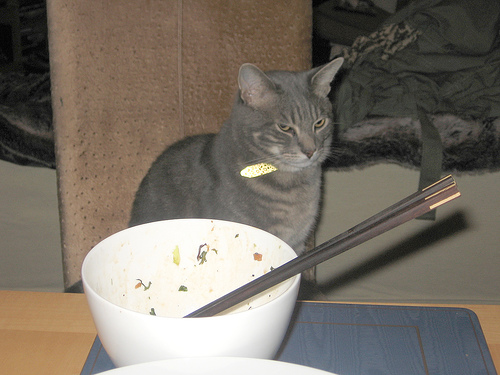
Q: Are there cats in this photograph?
A: Yes, there is a cat.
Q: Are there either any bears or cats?
A: Yes, there is a cat.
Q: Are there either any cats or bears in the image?
A: Yes, there is a cat.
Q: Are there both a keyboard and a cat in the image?
A: No, there is a cat but no keyboards.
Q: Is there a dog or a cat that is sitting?
A: Yes, the cat is sitting.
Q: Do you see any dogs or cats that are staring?
A: Yes, the cat is staring.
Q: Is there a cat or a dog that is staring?
A: Yes, the cat is staring.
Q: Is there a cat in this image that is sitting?
A: Yes, there is a cat that is sitting.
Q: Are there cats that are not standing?
A: Yes, there is a cat that is sitting.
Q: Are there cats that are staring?
A: Yes, there is a cat that is staring.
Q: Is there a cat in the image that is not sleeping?
A: Yes, there is a cat that is staring.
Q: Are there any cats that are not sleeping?
A: Yes, there is a cat that is staring.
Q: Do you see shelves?
A: No, there are no shelves.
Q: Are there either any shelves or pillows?
A: No, there are no shelves or pillows.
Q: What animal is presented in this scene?
A: The animal is a cat.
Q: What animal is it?
A: The animal is a cat.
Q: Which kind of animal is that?
A: That is a cat.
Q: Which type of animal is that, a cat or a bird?
A: That is a cat.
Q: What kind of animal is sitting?
A: The animal is a cat.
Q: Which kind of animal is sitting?
A: The animal is a cat.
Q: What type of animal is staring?
A: The animal is a cat.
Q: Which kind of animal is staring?
A: The animal is a cat.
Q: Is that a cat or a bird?
A: That is a cat.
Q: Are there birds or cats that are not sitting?
A: No, there is a cat but it is sitting.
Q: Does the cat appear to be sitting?
A: Yes, the cat is sitting.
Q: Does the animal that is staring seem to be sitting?
A: Yes, the cat is sitting.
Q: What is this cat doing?
A: The cat is sitting.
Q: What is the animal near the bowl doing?
A: The cat is sitting.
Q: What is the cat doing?
A: The cat is sitting.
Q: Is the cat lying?
A: No, the cat is sitting.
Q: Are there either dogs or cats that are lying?
A: No, there is a cat but it is sitting.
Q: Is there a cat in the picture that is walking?
A: No, there is a cat but it is sitting.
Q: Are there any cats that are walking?
A: No, there is a cat but it is sitting.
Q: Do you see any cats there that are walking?
A: No, there is a cat but it is sitting.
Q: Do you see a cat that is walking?
A: No, there is a cat but it is sitting.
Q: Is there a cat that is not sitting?
A: No, there is a cat but it is sitting.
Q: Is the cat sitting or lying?
A: The cat is sitting.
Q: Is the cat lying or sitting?
A: The cat is sitting.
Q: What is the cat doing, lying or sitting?
A: The cat is sitting.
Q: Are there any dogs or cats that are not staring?
A: No, there is a cat but it is staring.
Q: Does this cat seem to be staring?
A: Yes, the cat is staring.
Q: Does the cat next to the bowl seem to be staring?
A: Yes, the cat is staring.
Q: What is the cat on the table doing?
A: The cat is staring.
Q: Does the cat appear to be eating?
A: No, the cat is staring.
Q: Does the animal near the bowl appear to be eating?
A: No, the cat is staring.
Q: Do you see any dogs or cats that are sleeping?
A: No, there is a cat but it is staring.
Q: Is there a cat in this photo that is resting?
A: No, there is a cat but it is staring.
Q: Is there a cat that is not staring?
A: No, there is a cat but it is staring.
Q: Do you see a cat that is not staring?
A: No, there is a cat but it is staring.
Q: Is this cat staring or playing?
A: The cat is staring.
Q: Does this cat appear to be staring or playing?
A: The cat is staring.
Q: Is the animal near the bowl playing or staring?
A: The cat is staring.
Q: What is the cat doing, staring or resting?
A: The cat is staring.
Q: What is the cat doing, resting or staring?
A: The cat is staring.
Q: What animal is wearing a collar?
A: The cat is wearing a collar.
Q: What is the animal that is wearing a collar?
A: The animal is a cat.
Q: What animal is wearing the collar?
A: The animal is a cat.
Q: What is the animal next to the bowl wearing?
A: The cat is wearing a collar.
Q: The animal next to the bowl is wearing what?
A: The cat is wearing a collar.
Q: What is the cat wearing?
A: The cat is wearing a collar.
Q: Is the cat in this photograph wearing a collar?
A: Yes, the cat is wearing a collar.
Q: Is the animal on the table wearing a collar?
A: Yes, the cat is wearing a collar.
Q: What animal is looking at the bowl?
A: The cat is looking at the bowl.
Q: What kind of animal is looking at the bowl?
A: The animal is a cat.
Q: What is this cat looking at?
A: The cat is looking at the bowl.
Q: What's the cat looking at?
A: The cat is looking at the bowl.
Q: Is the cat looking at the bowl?
A: Yes, the cat is looking at the bowl.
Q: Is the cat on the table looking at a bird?
A: No, the cat is looking at the bowl.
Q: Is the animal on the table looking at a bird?
A: No, the cat is looking at the bowl.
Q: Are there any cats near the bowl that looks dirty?
A: Yes, there is a cat near the bowl.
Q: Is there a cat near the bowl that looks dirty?
A: Yes, there is a cat near the bowl.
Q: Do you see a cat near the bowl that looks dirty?
A: Yes, there is a cat near the bowl.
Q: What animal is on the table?
A: The cat is on the table.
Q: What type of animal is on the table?
A: The animal is a cat.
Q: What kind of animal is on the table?
A: The animal is a cat.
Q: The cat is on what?
A: The cat is on the table.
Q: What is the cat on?
A: The cat is on the table.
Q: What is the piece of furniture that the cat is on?
A: The piece of furniture is a table.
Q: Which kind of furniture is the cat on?
A: The cat is on the table.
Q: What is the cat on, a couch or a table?
A: The cat is on a table.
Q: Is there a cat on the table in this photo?
A: Yes, there is a cat on the table.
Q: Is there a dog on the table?
A: No, there is a cat on the table.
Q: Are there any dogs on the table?
A: No, there is a cat on the table.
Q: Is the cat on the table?
A: Yes, the cat is on the table.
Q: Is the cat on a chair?
A: No, the cat is on the table.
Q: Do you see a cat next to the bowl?
A: Yes, there is a cat next to the bowl.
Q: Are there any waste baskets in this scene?
A: No, there are no waste baskets.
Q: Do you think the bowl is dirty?
A: Yes, the bowl is dirty.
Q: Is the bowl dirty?
A: Yes, the bowl is dirty.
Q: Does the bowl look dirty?
A: Yes, the bowl is dirty.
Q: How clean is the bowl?
A: The bowl is dirty.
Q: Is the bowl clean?
A: No, the bowl is dirty.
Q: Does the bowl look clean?
A: No, the bowl is dirty.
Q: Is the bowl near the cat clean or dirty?
A: The bowl is dirty.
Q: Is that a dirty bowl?
A: Yes, that is a dirty bowl.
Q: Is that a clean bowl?
A: No, that is a dirty bowl.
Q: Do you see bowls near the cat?
A: Yes, there is a bowl near the cat.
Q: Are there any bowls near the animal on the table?
A: Yes, there is a bowl near the cat.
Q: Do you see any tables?
A: Yes, there is a table.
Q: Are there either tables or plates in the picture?
A: Yes, there is a table.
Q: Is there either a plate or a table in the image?
A: Yes, there is a table.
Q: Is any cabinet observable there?
A: No, there are no cabinets.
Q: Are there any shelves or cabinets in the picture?
A: No, there are no cabinets or shelves.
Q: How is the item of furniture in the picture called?
A: The piece of furniture is a table.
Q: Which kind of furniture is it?
A: The piece of furniture is a table.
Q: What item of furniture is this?
A: That is a table.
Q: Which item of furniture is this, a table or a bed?
A: That is a table.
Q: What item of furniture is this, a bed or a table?
A: That is a table.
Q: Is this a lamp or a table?
A: This is a table.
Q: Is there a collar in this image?
A: Yes, there is a collar.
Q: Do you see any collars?
A: Yes, there is a collar.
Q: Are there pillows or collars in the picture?
A: Yes, there is a collar.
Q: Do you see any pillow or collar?
A: Yes, there is a collar.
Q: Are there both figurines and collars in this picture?
A: No, there is a collar but no figurines.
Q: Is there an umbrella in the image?
A: No, there are no umbrellas.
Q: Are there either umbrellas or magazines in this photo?
A: No, there are no umbrellas or magazines.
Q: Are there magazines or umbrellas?
A: No, there are no umbrellas or magazines.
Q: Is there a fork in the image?
A: No, there are no forks.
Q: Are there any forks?
A: No, there are no forks.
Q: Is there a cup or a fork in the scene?
A: No, there are no forks or cups.